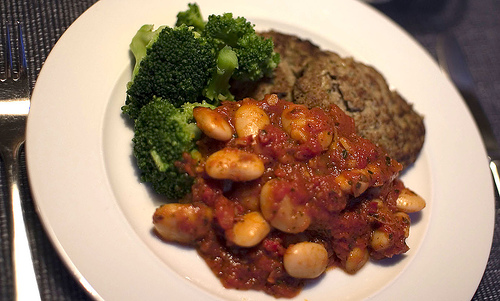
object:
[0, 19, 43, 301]
fork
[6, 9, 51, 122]
mat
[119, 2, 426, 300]
food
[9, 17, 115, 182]
sign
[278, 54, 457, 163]
meat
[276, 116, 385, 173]
sauce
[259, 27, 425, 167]
hamburgers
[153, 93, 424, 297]
bean casserole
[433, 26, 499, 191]
knife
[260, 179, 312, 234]
bean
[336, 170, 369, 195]
bean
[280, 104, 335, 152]
bean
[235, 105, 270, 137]
bean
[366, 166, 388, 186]
bean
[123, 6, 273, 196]
broccoli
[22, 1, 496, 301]
plate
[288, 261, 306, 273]
bad sentence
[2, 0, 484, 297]
photo